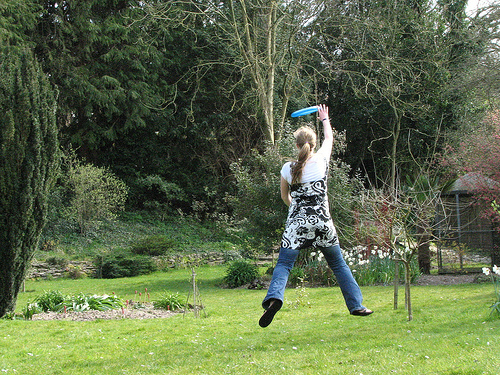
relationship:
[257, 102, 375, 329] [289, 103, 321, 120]
person grabbing frisbee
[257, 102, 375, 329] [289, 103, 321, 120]
person holding frisbee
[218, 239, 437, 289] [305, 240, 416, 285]
patch of flowers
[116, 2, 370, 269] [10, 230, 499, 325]
tree in a garden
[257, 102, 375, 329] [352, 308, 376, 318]
person has a sandal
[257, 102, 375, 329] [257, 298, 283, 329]
person has a left foot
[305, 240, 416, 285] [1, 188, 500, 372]
flowers in a field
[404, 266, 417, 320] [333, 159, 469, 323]
trunk of tree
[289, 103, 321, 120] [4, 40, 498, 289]
frisbee in air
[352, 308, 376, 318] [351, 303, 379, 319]
sandal on foot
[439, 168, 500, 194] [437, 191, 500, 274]
roof on gazebo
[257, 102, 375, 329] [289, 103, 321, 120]
person catching frisbee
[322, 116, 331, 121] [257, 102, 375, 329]
accessory on woman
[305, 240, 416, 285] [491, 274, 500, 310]
flowers on stems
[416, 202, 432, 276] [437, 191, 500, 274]
beam for gazebo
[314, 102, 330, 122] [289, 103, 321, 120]
hand reaching for frisbee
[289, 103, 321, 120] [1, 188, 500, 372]
frisbee in field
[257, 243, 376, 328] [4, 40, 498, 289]
legs in air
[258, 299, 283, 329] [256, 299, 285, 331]
sole of her sandal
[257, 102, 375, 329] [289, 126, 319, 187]
person has hair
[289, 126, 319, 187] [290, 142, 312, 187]
hair in ponytail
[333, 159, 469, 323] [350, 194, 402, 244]
trees with no leaves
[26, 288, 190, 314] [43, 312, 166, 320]
plants in mulch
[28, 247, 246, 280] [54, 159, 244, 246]
rock wall against hill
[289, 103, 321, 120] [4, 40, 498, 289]
frisbee flying in air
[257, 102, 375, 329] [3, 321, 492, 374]
person playing on grass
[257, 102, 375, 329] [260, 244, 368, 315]
person has jeans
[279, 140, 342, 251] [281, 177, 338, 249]
shirt with design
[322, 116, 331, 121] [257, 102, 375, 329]
accessory worn by person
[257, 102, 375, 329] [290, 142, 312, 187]
person has ponytail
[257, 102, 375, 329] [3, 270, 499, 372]
person jumping off ground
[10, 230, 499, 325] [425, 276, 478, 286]
garden with rocks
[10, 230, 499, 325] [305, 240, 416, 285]
garden with flowers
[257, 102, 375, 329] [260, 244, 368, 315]
person wearing jeans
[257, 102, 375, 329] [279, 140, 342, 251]
person wearing shirt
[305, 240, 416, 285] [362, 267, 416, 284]
flowers with leaves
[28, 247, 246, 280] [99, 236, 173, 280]
rock wall with bushes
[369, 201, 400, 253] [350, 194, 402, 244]
branches with no leaves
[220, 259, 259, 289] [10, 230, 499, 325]
bush by garden